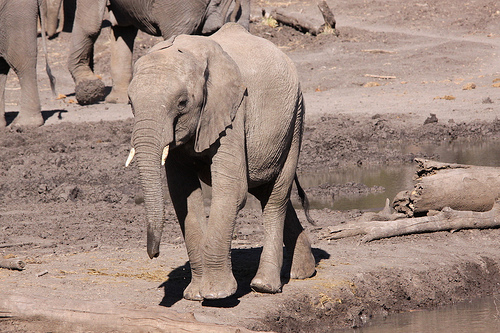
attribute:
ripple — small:
[459, 306, 489, 327]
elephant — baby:
[121, 20, 318, 304]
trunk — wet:
[131, 106, 174, 258]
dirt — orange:
[335, 30, 497, 135]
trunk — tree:
[327, 201, 499, 244]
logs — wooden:
[333, 210, 493, 239]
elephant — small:
[89, 30, 355, 302]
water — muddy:
[334, 294, 484, 329]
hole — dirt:
[277, 264, 493, 331]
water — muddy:
[306, 157, 407, 207]